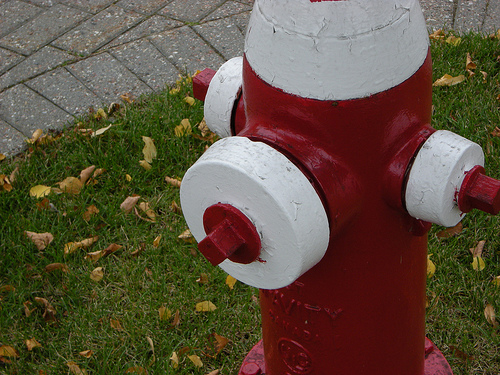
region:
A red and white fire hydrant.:
[178, 1, 498, 373]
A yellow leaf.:
[26, 184, 63, 199]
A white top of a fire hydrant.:
[243, 0, 430, 100]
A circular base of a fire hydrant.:
[238, 333, 450, 374]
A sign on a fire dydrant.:
[261, 278, 339, 373]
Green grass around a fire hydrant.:
[0, 33, 499, 371]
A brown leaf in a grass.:
[24, 228, 52, 253]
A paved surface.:
[2, 0, 499, 159]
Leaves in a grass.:
[30, 164, 106, 199]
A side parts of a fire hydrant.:
[179, 136, 331, 288]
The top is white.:
[232, 2, 444, 101]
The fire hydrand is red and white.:
[178, 3, 490, 372]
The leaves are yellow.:
[17, 123, 174, 351]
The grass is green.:
[0, 95, 225, 373]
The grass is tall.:
[0, 99, 225, 369]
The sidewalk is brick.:
[3, 0, 225, 147]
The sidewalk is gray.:
[0, 1, 229, 124]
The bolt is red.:
[193, 213, 258, 277]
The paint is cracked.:
[251, 5, 416, 52]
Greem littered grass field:
[33, 169, 155, 308]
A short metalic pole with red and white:
[252, 18, 422, 373]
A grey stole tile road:
[10, 76, 101, 127]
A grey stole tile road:
[72, 56, 174, 85]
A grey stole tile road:
[2, 2, 119, 44]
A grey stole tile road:
[430, 5, 497, 35]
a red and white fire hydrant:
[178, 1, 498, 371]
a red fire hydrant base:
[235, 330, 455, 370]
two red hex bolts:
[240, 331, 445, 371]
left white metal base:
[175, 132, 326, 287]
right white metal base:
[401, 127, 486, 227]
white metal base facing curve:
[200, 45, 240, 135]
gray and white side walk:
[0, 36, 242, 161]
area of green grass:
[0, 30, 496, 371]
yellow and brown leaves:
[0, 25, 497, 370]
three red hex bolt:
[190, 63, 497, 268]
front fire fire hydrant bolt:
[195, 200, 260, 265]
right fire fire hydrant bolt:
[456, 165, 496, 218]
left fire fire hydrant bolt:
[188, 65, 219, 100]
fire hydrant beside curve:
[178, 0, 494, 372]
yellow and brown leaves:
[1, 27, 498, 374]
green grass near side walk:
[0, 32, 499, 373]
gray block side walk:
[2, 2, 499, 161]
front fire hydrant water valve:
[179, 132, 331, 291]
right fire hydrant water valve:
[404, 127, 486, 229]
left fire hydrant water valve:
[201, 54, 246, 139]